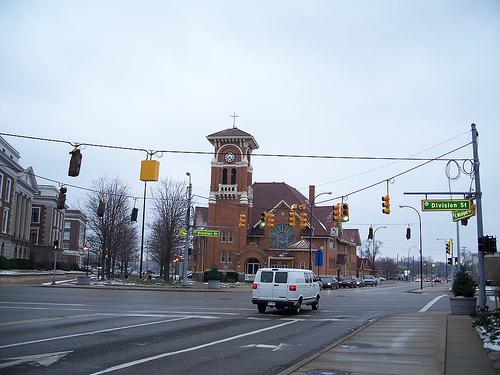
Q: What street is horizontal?
A: Division St.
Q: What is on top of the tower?
A: A cross.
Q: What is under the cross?
A: A clock.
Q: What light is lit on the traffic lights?
A: The green light.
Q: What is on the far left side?
A: Buildings.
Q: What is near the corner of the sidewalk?
A: A big potted plant.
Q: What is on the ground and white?
A: Snow.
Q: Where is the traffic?
A: Street.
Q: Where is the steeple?
A: Church.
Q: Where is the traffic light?
A: Above.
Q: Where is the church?
A: Back of street.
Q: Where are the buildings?
A: Alone street.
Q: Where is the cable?
A: Over street.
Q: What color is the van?
A: White.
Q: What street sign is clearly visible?
A: Division street.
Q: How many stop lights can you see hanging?
A: 15.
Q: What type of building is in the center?
A: A church.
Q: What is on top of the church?
A: A cross.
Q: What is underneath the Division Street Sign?
A: A plant.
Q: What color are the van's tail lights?
A: Red.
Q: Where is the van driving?
A: On the street.